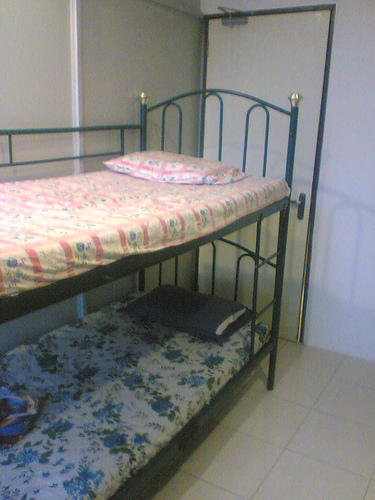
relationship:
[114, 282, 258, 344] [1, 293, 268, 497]
pillow on bed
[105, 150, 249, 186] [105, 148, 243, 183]
bed pillow with pillowcase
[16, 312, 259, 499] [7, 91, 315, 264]
sheet on bed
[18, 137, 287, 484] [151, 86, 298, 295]
bunk bed has metal frame